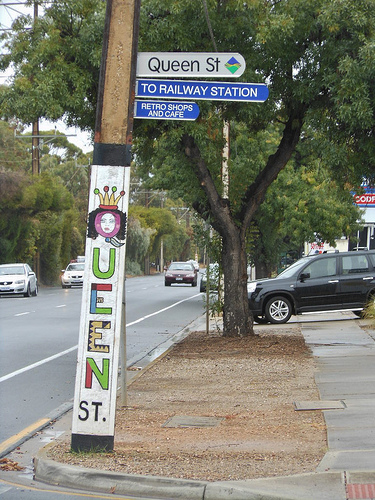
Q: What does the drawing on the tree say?
A: Queen St.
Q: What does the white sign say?
A: Queen st.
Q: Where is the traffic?
A: On the left?.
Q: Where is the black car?
A: On the sidewalk.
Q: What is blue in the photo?
A: The street sign.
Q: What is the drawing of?
A: A queen.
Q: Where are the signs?
A: On a pole.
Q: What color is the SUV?
A: Black.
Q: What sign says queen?
A: The tall, vertical one.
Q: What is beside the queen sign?
A: Gravel.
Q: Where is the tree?
A: Next to the road.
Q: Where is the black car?
A: On a sidewalk.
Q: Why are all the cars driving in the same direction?
A: It is a one-way street.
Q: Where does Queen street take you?
A: To railway station.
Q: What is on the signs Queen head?
A: A crown.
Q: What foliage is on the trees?
A: Green leaves.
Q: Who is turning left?
A: A black SUV.